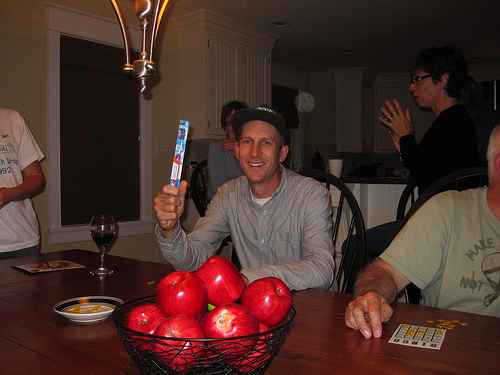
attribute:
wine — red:
[90, 229, 117, 248]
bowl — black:
[109, 290, 298, 372]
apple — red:
[153, 269, 207, 318]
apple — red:
[190, 251, 244, 304]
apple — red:
[239, 274, 293, 325]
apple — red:
[123, 301, 163, 351]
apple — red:
[150, 313, 204, 370]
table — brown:
[6, 306, 486, 367]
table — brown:
[20, 248, 144, 292]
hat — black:
[222, 101, 306, 143]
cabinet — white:
[197, 20, 275, 163]